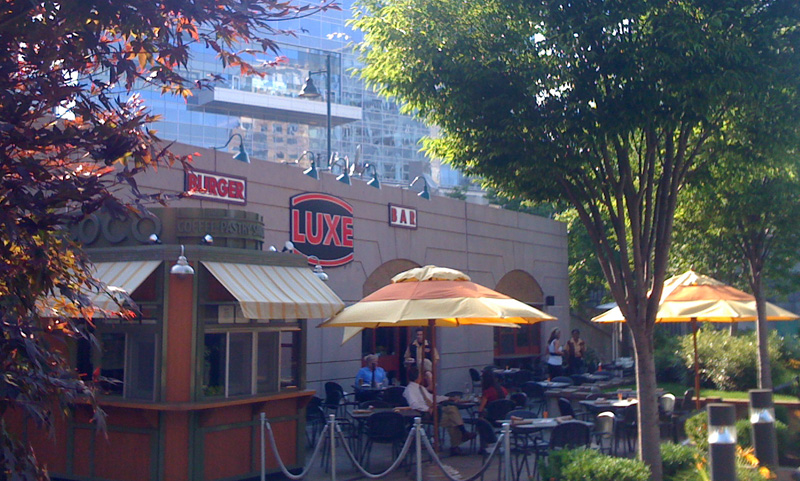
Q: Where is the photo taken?
A: At Luxe Burger Bar.